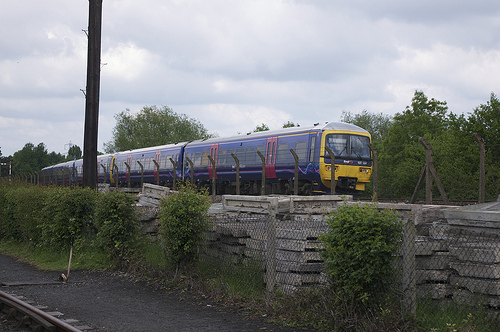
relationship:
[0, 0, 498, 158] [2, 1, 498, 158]
clouds in sky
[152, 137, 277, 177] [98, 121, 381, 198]
doors on train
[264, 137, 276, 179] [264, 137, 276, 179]
red door on red door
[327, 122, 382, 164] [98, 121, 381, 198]
windows on train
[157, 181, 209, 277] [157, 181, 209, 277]
bush on bush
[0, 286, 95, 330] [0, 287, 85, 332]
ties on ties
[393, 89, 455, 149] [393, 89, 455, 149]
leaves on leaves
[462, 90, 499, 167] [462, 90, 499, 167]
leaves on leaves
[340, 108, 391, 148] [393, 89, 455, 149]
leaves on leaves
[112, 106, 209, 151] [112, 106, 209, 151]
leaves on leaves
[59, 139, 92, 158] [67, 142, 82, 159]
tree on leaves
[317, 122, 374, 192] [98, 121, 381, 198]
windows on train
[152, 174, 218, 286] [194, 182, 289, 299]
bush by wall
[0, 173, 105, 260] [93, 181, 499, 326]
bush by wall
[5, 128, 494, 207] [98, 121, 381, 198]
fence on train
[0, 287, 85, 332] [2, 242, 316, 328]
ties on ground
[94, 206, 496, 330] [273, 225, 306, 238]
fence on concrete block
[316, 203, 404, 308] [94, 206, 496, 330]
bushes on fence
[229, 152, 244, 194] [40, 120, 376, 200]
wooden posts on woodfence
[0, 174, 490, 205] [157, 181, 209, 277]
train tracks are on side of bush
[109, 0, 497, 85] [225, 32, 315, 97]
clouds are in sky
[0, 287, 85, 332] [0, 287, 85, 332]
ties has ties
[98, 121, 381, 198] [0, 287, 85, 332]
train on ties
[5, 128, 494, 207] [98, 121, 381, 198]
fence alongside train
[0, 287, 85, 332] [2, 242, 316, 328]
ties are on ground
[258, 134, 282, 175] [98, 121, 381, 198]
red door on train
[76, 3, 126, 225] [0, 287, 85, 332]
pole on side of ties